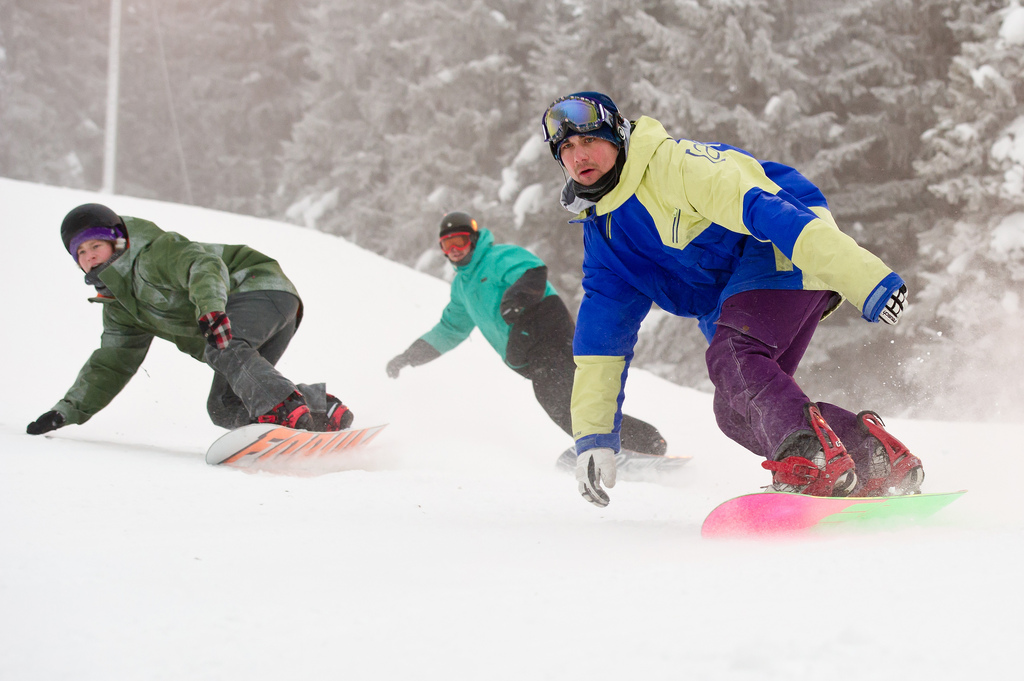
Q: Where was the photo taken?
A: Ski slope.